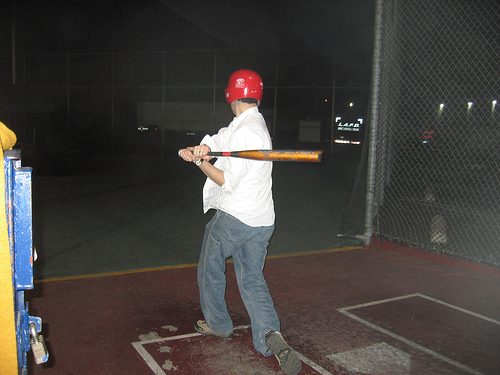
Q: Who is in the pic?
A: A man.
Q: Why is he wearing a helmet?
A: For protection.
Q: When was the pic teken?
A: At night.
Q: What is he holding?
A: A bat.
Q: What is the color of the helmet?
A: Red.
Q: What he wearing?
A: Sneakers.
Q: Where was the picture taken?
A: At a batting cage.